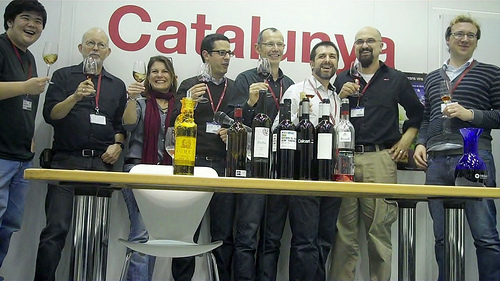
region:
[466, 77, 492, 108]
part of a sweater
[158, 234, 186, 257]
edge of a chair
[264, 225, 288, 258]
part of a trouser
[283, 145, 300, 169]
part of a bottle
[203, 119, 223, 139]
part of a tag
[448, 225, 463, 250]
part of a post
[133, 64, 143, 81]
part of a glass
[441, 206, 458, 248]
part of a stand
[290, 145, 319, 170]
part of a bottle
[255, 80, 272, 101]
part of a hand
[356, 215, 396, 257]
part of a trouser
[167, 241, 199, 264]
edge of a chair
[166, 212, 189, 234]
part of a chair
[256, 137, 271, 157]
part of a label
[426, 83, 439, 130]
part of a sweater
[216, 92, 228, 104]
part of a ribbon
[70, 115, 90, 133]
part of a shirt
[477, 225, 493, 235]
part of a jeans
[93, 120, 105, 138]
part of a tag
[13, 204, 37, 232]
part of a wall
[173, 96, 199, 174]
this is a bottle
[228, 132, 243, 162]
the bottle is glass made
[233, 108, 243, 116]
the lid is red in color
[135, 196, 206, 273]
this is a chair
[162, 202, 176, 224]
the chair is white in color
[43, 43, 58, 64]
this is a glass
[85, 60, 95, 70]
the glass is shinny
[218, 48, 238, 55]
this is a spectacle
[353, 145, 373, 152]
this is a belt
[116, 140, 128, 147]
this is a wrist watch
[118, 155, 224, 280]
a white chair with a plastic seat and back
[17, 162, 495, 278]
a long table with metal legs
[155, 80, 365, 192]
bottles of alcohol on a table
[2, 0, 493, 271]
people posing behind table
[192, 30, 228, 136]
man wearing a name tag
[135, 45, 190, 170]
dark red scarf around woman's neck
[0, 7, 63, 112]
man holding a wine glass from the bottom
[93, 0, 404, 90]
red text on wall behind several people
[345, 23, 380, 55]
man wearing glasses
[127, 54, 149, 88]
yellow liquid in glass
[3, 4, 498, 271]
eight people preparing for a toast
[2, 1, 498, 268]
8 people holding wine glasses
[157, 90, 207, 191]
the very yellow bottle of wine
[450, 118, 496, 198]
a blue carafe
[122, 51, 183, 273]
the only woman in the group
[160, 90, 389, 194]
bottles of wine on a table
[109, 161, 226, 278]
an empty white chair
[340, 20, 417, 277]
the man with a brown mustache, goatee, and glasses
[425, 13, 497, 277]
the man wearing a striped V-neck sweater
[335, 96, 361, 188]
the almost empty bottle of rose